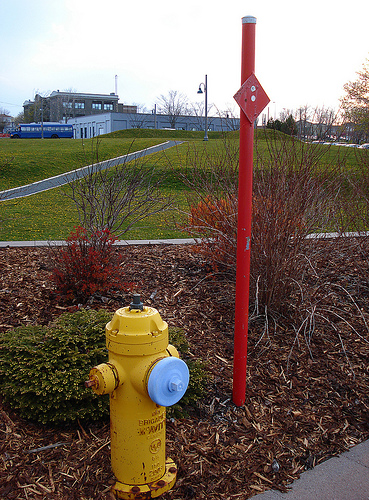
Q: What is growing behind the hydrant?
A: Bush.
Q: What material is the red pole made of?
A: Metal.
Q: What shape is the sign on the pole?
A: Diamond.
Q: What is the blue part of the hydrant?
A: Cap.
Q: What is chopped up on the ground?
A: Mulch.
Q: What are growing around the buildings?
A: Trees.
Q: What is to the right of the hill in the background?
A: Parking lot.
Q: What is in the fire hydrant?
A: Water.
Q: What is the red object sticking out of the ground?
A: A metal pole.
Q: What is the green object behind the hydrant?
A: A bush.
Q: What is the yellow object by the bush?
A: A hydrant.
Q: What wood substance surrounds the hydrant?
A: Mulch.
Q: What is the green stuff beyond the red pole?
A: Grass.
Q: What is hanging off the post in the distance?
A: A lamp.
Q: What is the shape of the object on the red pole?
A: A diamond.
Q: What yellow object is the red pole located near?
A: A hydrant.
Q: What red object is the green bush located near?
A: A metal pole.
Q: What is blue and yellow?
A: Fire hydrant.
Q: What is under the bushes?
A: Mulch.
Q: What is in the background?
A: Two separate sections of a school building.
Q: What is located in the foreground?
A: Fire hydrant.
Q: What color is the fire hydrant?
A: Yellow.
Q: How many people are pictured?
A: None.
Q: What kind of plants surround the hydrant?
A: Bushes.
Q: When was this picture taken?
A: Daytime.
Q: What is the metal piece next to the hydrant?
A: Pole.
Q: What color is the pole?
A: Red.